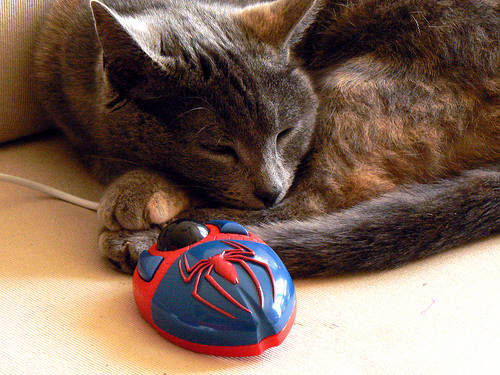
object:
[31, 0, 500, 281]
cat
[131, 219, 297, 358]
mouse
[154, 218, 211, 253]
ball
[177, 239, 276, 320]
spider